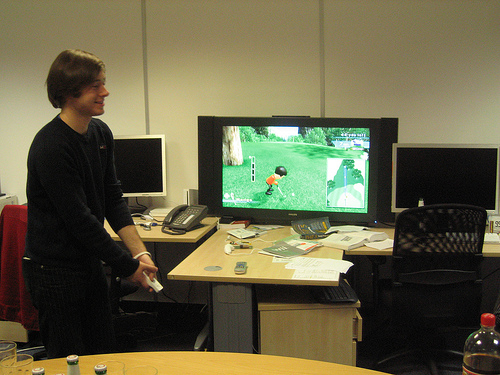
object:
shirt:
[27, 121, 132, 261]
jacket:
[1, 203, 51, 335]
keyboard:
[316, 282, 357, 305]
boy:
[15, 41, 168, 360]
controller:
[138, 266, 165, 295]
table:
[166, 219, 499, 284]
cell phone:
[232, 257, 252, 277]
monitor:
[102, 133, 167, 198]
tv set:
[195, 112, 394, 225]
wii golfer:
[263, 165, 286, 199]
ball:
[290, 193, 295, 197]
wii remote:
[131, 249, 164, 295]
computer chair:
[386, 203, 499, 350]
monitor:
[396, 141, 498, 219]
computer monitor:
[110, 131, 170, 199]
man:
[8, 41, 161, 343]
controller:
[136, 264, 160, 295]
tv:
[197, 117, 395, 216]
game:
[215, 128, 368, 213]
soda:
[465, 354, 497, 372]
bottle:
[454, 305, 499, 370]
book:
[316, 225, 378, 252]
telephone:
[159, 198, 210, 235]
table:
[103, 201, 220, 244]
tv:
[196, 113, 387, 229]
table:
[174, 202, 393, 300]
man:
[20, 47, 161, 357]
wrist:
[130, 243, 152, 270]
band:
[127, 247, 154, 261]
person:
[20, 44, 160, 357]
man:
[16, 42, 170, 372]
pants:
[21, 254, 127, 356]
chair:
[365, 204, 494, 374]